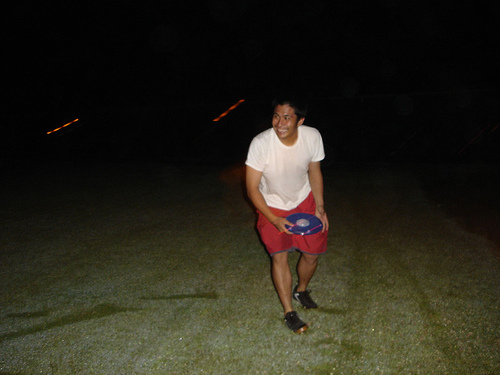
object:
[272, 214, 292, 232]
hand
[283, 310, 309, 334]
feet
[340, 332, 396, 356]
turf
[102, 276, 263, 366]
ground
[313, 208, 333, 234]
hand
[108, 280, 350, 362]
lines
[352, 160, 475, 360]
ground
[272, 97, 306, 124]
hair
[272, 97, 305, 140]
head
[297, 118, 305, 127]
ear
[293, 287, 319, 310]
foot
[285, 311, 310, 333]
shoe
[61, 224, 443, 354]
tracks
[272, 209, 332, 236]
freesbie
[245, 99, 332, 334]
guy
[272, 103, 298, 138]
face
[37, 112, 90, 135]
lights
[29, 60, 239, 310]
field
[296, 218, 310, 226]
circle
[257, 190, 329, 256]
shorts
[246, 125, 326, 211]
shirt